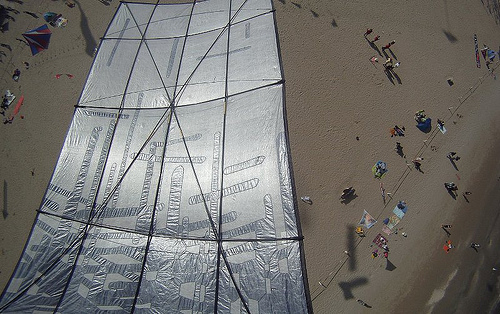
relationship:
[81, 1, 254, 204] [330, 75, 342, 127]
kite on beach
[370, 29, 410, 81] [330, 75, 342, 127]
peopel on beach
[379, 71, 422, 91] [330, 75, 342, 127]
shadows on beach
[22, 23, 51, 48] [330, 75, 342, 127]
tent on beach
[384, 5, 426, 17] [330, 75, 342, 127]
sand at beach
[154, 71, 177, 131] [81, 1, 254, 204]
lines on kite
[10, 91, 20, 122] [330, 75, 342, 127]
blanket on beach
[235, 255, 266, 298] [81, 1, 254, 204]
pole for kite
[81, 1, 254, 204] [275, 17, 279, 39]
kite in air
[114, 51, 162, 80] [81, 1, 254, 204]
design on kite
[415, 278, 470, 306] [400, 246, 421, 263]
wave on shore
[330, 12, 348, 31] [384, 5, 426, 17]
rut in sand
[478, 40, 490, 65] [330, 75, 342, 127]
person on beach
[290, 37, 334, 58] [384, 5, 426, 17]
footprints on sand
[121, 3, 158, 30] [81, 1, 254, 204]
strut of kite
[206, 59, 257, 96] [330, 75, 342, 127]
poster on beach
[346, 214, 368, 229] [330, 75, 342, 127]
towel on beach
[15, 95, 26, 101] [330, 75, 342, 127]
object on beach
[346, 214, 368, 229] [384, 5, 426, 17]
towel on sand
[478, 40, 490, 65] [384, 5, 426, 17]
person on sand